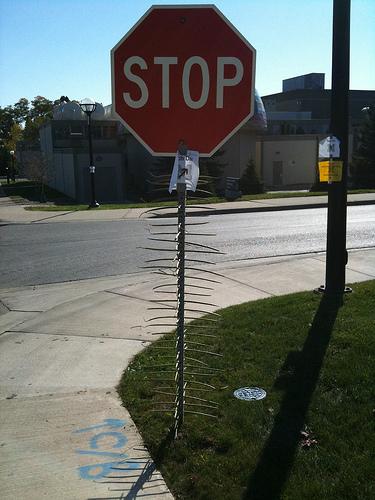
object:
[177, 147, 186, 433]
pole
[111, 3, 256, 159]
sign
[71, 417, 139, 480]
graffiti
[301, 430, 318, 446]
leaf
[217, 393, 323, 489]
grass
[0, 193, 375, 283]
road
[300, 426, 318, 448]
leave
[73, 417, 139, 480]
letter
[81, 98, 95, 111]
bulb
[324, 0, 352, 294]
pole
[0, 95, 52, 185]
tree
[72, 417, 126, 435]
arrow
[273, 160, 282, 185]
door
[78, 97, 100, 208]
lamp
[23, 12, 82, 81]
sky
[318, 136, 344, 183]
paper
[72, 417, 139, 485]
paint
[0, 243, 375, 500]
sidewalk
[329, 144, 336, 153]
spikes